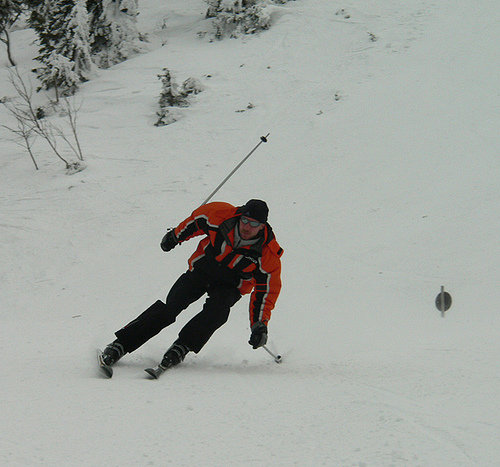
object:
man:
[99, 200, 285, 385]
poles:
[182, 136, 309, 373]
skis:
[96, 345, 115, 378]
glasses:
[240, 215, 263, 227]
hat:
[242, 198, 269, 223]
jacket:
[175, 201, 284, 326]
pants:
[115, 268, 244, 353]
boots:
[101, 337, 130, 366]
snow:
[1, 3, 499, 461]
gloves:
[248, 322, 269, 350]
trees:
[34, 0, 98, 97]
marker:
[435, 290, 453, 312]